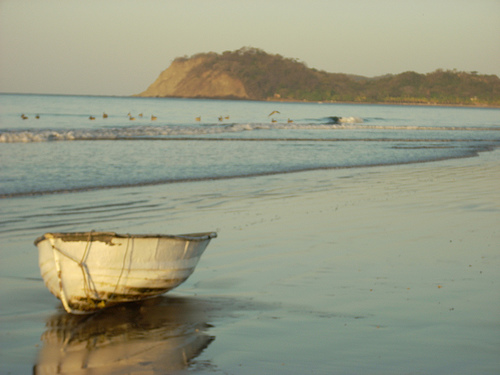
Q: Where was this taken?
A: At a beach.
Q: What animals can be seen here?
A: Birds.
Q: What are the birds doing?
A: Flying.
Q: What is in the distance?
A: A peninsula of land.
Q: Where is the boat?
A: On the shore.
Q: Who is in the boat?
A: No one.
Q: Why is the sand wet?
A: The waves are coming in.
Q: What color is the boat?
A: White.